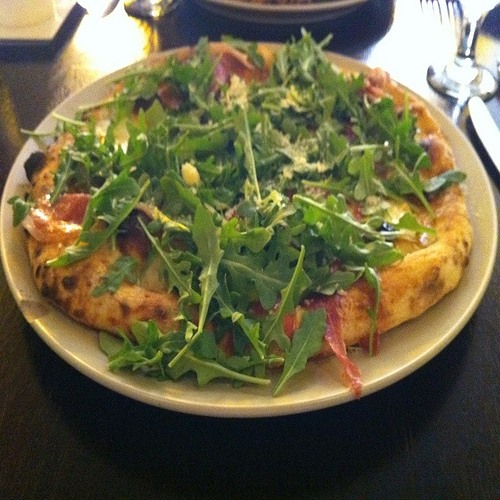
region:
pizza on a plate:
[32, 35, 473, 375]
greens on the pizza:
[43, 29, 428, 387]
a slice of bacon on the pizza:
[317, 281, 377, 398]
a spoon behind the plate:
[420, 13, 498, 97]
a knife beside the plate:
[464, 92, 499, 180]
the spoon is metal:
[425, 9, 497, 104]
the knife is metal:
[458, 84, 496, 186]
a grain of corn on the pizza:
[180, 163, 210, 191]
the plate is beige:
[0, 44, 495, 419]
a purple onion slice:
[201, 51, 233, 92]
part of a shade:
[361, 402, 416, 464]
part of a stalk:
[278, 368, 308, 387]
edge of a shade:
[401, 407, 460, 443]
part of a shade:
[362, 415, 401, 481]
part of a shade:
[377, 408, 402, 448]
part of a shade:
[378, 405, 397, 433]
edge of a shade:
[407, 415, 435, 448]